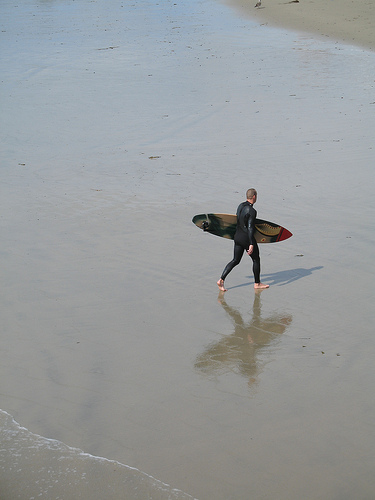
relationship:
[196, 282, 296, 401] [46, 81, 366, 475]
reflection on sand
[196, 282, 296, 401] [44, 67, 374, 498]
reflection on sand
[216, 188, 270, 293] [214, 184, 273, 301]
man wearing wetsuit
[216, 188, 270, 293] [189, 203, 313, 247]
man holds a surfboard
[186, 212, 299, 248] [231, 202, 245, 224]
surfboard under left arm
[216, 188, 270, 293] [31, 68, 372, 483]
man walking in water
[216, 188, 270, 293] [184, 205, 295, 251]
man carrying surfboard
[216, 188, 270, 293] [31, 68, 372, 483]
man walking away from water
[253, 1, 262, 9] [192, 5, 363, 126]
bird near water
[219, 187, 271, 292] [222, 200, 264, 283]
man wearing suit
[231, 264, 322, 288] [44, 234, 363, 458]
shadow on ground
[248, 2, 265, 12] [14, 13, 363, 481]
bird on sand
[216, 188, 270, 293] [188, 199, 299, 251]
man holding surfboard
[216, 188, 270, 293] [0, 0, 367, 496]
man by sea shore